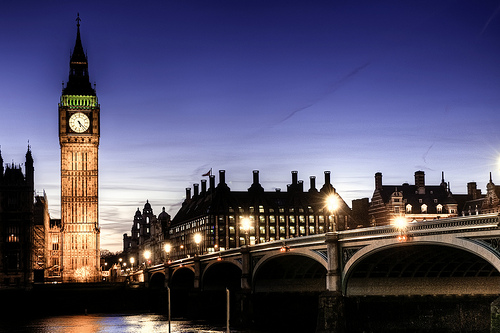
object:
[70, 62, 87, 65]
lights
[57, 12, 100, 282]
clock tower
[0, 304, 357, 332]
water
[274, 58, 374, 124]
airplane trail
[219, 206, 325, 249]
windows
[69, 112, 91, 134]
clock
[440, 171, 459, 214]
turret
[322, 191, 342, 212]
light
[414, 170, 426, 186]
chimney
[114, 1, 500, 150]
sky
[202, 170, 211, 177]
flag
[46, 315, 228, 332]
lights reflection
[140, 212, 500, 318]
bridge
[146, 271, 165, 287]
arch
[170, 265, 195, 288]
arch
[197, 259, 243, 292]
arch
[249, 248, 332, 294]
arch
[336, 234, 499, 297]
arch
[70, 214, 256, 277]
lights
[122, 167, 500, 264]
building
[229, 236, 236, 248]
window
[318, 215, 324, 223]
window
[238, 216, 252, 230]
window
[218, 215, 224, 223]
window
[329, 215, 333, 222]
window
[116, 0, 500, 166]
ground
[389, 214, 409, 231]
light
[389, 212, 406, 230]
bright light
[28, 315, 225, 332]
blue light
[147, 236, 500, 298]
arches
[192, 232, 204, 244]
globe light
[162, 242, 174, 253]
globe light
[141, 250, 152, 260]
globe light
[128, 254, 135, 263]
globe light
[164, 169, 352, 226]
roof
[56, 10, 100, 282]
tower